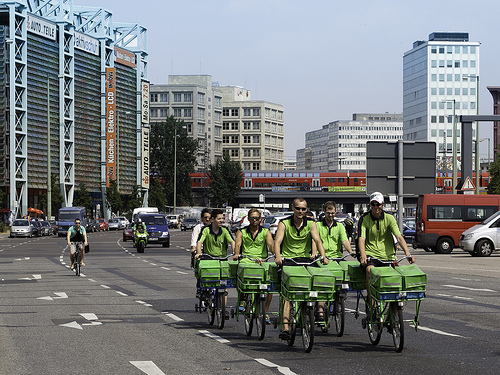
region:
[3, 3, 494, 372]
A city highway scene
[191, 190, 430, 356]
These people are riding bicycles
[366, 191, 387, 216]
This man is wearing a hat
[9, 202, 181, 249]
Vehicle traffic is in the background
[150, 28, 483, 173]
Buildings are in the distance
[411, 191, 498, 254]
A red van is parked here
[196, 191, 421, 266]
These people are wearing green shirts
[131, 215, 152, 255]
This person is riding a motorcycle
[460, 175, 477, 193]
A street sign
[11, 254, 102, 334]
Arrows are painted on the street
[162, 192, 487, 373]
group of bikes riding together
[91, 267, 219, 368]
Paint on the road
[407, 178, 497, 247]
Red bus parked in the lot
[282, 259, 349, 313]
Front of the bike is green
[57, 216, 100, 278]
Bike riding down the road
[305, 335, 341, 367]
The road is wet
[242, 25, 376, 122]
The sky is blue no clouds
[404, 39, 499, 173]
tall building in the background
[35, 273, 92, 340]
Arrows on the road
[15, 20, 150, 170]
Building in the background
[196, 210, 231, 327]
a man riding a bicycle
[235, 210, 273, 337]
a man riding a bicycle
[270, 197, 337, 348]
a man riding a bicycle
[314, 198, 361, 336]
a man riding a bicycle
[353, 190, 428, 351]
a man riding a bicycle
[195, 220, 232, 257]
a green and black shirt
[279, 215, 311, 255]
a green and black shirta green and black shirt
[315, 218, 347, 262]
a green and black shirt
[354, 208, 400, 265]
a green and black shirt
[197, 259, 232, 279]
a green bicycle basket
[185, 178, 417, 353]
a group of men on bicycles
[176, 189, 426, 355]
bicyclists wearing the same shirt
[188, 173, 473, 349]
green bicycles with green baskets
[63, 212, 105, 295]
a man biking down the street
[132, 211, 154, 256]
a person on a motorcycle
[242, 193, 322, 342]
men on green bicycles wearing sunglasses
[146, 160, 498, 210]
A red subway train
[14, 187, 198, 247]
cars driving in traffic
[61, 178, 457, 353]
bicyclists biking in traffic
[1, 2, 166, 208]
a tall blue building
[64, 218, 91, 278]
A lone bicycle rider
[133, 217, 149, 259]
A rider on a motorbike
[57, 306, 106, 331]
A white arrow on the road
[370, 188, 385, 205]
A white cap on the head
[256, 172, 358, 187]
A train passing over a bridge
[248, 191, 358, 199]
A bridge over the road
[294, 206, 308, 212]
Black shades covering the eyes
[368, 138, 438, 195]
The back of a bill board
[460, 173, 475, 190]
A traffic sign in the distance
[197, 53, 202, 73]
A mast on top of a building